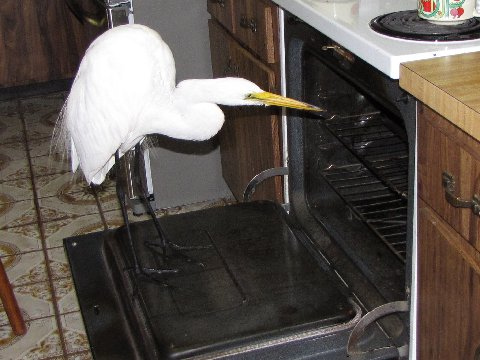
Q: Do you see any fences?
A: No, there are no fences.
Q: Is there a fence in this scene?
A: No, there are no fences.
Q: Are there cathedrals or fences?
A: No, there are no fences or cathedrals.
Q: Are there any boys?
A: No, there are no boys.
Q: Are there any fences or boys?
A: No, there are no boys or fences.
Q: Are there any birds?
A: Yes, there is a bird.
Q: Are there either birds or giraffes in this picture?
A: Yes, there is a bird.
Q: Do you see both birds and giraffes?
A: No, there is a bird but no giraffes.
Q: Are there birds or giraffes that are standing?
A: Yes, the bird is standing.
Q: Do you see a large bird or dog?
A: Yes, there is a large bird.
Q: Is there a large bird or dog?
A: Yes, there is a large bird.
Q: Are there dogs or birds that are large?
A: Yes, the bird is large.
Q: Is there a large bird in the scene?
A: Yes, there is a large bird.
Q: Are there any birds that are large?
A: Yes, there is a bird that is large.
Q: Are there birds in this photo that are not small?
A: Yes, there is a large bird.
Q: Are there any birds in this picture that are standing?
A: Yes, there is a bird that is standing.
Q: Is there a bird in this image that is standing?
A: Yes, there is a bird that is standing.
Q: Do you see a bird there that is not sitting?
A: Yes, there is a bird that is standing .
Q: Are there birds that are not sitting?
A: Yes, there is a bird that is standing.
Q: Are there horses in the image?
A: No, there are no horses.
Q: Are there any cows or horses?
A: No, there are no horses or cows.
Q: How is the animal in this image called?
A: The animal is a bird.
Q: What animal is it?
A: The animal is a bird.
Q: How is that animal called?
A: This is a bird.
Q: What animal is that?
A: This is a bird.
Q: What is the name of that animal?
A: This is a bird.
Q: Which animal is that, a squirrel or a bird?
A: This is a bird.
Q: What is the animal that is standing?
A: The animal is a bird.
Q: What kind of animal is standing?
A: The animal is a bird.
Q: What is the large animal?
A: The animal is a bird.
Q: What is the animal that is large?
A: The animal is a bird.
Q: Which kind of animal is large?
A: The animal is a bird.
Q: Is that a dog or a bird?
A: That is a bird.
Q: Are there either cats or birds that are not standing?
A: No, there is a bird but it is standing.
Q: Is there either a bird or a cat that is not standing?
A: No, there is a bird but it is standing.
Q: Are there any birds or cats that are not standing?
A: No, there is a bird but it is standing.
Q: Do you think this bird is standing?
A: Yes, the bird is standing.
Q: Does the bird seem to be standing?
A: Yes, the bird is standing.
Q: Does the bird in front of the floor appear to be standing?
A: Yes, the bird is standing.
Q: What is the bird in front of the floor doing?
A: The bird is standing.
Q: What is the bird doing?
A: The bird is standing.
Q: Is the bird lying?
A: No, the bird is standing.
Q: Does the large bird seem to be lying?
A: No, the bird is standing.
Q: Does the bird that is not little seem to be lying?
A: No, the bird is standing.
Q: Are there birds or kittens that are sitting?
A: No, there is a bird but it is standing.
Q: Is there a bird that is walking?
A: No, there is a bird but it is standing.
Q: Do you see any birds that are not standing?
A: No, there is a bird but it is standing.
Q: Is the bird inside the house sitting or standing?
A: The bird is standing.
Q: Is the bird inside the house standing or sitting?
A: The bird is standing.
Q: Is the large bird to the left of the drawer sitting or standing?
A: The bird is standing.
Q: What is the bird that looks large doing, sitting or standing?
A: The bird is standing.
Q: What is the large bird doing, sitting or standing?
A: The bird is standing.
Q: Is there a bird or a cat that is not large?
A: No, there is a bird but it is large.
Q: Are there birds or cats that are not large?
A: No, there is a bird but it is large.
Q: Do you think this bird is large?
A: Yes, the bird is large.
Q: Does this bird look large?
A: Yes, the bird is large.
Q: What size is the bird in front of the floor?
A: The bird is large.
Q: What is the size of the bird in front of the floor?
A: The bird is large.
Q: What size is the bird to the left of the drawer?
A: The bird is large.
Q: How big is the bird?
A: The bird is large.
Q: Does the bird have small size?
A: No, the bird is large.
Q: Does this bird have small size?
A: No, the bird is large.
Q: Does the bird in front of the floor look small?
A: No, the bird is large.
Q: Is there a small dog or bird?
A: No, there is a bird but it is large.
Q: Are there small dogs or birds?
A: No, there is a bird but it is large.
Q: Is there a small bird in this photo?
A: No, there is a bird but it is large.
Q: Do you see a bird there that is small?
A: No, there is a bird but it is large.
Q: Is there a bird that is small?
A: No, there is a bird but it is large.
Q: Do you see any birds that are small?
A: No, there is a bird but it is large.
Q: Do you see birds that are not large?
A: No, there is a bird but it is large.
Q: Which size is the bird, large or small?
A: The bird is large.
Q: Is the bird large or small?
A: The bird is large.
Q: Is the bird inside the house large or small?
A: The bird is large.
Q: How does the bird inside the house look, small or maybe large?
A: The bird is large.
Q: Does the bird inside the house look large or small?
A: The bird is large.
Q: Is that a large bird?
A: Yes, that is a large bird.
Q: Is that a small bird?
A: No, that is a large bird.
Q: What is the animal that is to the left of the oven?
A: The animal is a bird.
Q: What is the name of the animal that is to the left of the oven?
A: The animal is a bird.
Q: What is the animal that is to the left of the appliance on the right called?
A: The animal is a bird.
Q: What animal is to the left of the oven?
A: The animal is a bird.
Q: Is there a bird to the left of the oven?
A: Yes, there is a bird to the left of the oven.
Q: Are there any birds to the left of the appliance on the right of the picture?
A: Yes, there is a bird to the left of the oven.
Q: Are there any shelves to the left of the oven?
A: No, there is a bird to the left of the oven.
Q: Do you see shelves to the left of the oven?
A: No, there is a bird to the left of the oven.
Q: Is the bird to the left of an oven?
A: Yes, the bird is to the left of an oven.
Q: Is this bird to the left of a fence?
A: No, the bird is to the left of an oven.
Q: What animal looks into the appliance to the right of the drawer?
A: The bird looks into the oven.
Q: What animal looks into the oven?
A: The bird looks into the oven.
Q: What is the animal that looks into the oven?
A: The animal is a bird.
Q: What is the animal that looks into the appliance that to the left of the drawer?
A: The animal is a bird.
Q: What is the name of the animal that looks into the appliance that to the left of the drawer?
A: The animal is a bird.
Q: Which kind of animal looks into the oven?
A: The animal is a bird.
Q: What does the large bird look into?
A: The bird looks into the oven.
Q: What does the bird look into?
A: The bird looks into the oven.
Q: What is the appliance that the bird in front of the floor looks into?
A: The appliance is an oven.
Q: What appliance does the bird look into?
A: The bird looks into the oven.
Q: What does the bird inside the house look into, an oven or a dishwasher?
A: The bird looks into an oven.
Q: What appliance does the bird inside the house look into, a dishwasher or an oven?
A: The bird looks into an oven.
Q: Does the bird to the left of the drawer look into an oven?
A: Yes, the bird looks into an oven.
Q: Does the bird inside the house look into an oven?
A: Yes, the bird looks into an oven.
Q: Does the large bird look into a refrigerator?
A: No, the bird looks into an oven.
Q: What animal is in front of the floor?
A: The bird is in front of the floor.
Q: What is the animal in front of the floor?
A: The animal is a bird.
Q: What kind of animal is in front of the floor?
A: The animal is a bird.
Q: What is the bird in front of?
A: The bird is in front of the floor.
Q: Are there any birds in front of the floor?
A: Yes, there is a bird in front of the floor.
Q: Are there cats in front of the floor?
A: No, there is a bird in front of the floor.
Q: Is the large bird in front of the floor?
A: Yes, the bird is in front of the floor.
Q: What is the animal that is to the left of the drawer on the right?
A: The animal is a bird.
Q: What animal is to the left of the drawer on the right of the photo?
A: The animal is a bird.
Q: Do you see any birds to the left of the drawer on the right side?
A: Yes, there is a bird to the left of the drawer.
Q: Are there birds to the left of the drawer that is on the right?
A: Yes, there is a bird to the left of the drawer.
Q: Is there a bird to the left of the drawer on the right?
A: Yes, there is a bird to the left of the drawer.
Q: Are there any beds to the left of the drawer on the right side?
A: No, there is a bird to the left of the drawer.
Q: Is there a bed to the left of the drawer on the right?
A: No, there is a bird to the left of the drawer.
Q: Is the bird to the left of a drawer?
A: Yes, the bird is to the left of a drawer.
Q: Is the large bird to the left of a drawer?
A: Yes, the bird is to the left of a drawer.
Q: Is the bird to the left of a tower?
A: No, the bird is to the left of a drawer.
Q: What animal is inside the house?
A: The bird is inside the house.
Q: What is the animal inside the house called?
A: The animal is a bird.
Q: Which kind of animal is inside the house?
A: The animal is a bird.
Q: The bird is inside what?
A: The bird is inside the house.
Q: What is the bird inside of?
A: The bird is inside the house.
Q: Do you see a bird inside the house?
A: Yes, there is a bird inside the house.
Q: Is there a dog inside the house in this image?
A: No, there is a bird inside the house.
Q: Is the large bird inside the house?
A: Yes, the bird is inside the house.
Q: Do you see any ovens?
A: Yes, there is an oven.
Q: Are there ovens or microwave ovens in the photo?
A: Yes, there is an oven.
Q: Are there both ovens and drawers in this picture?
A: Yes, there are both an oven and a drawer.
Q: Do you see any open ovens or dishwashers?
A: Yes, there is an open oven.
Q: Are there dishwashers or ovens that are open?
A: Yes, the oven is open.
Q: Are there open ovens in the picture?
A: Yes, there is an open oven.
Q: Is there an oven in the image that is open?
A: Yes, there is an oven that is open.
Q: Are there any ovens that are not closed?
A: Yes, there is a open oven.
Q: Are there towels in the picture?
A: No, there are no towels.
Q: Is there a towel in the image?
A: No, there are no towels.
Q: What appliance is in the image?
A: The appliance is an oven.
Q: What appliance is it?
A: The appliance is an oven.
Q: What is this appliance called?
A: This is an oven.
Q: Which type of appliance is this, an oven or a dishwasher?
A: This is an oven.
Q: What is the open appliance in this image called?
A: The appliance is an oven.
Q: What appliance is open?
A: The appliance is an oven.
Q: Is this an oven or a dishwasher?
A: This is an oven.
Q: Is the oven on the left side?
A: No, the oven is on the right of the image.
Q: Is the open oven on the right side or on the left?
A: The oven is on the right of the image.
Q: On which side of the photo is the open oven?
A: The oven is on the right of the image.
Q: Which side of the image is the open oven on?
A: The oven is on the right of the image.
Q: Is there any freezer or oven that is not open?
A: No, there is an oven but it is open.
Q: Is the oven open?
A: Yes, the oven is open.